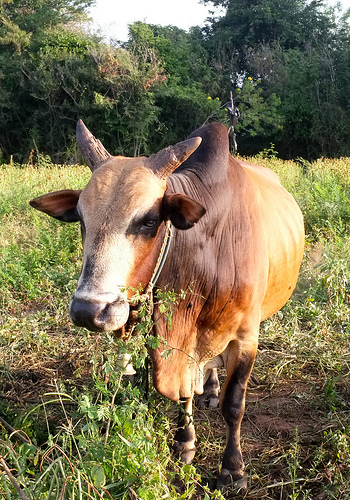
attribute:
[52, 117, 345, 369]
boar — brown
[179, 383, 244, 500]
legs — brown, covered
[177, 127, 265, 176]
hump — brown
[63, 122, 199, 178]
horns — brown, pointed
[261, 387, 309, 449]
patch — brown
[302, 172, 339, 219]
grass — green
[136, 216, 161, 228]
eye — patch, black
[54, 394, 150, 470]
bushes — unkempt, green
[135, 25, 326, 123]
trees — tall, green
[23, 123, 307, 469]
cow — big, standing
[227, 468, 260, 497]
hoof — black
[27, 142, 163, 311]
head — white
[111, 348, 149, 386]
bell — hanging, silver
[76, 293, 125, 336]
nose — wet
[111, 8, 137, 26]
sky — blue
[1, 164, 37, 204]
weeds — long